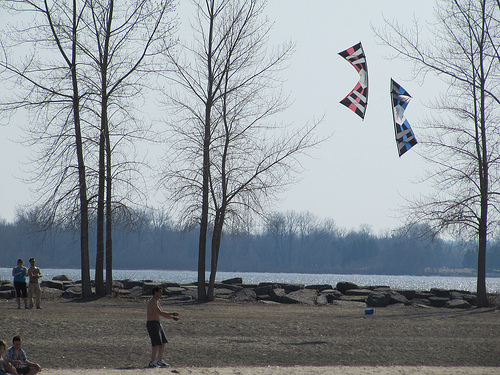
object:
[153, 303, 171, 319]
arm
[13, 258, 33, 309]
person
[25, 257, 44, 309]
person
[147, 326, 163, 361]
legs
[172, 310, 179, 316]
hand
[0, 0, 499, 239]
sky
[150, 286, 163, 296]
head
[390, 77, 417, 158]
kite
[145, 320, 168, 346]
shorts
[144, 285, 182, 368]
man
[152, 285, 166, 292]
hair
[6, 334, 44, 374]
children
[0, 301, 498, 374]
ground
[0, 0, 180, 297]
tree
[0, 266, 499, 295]
lake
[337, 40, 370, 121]
kite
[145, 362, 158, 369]
foot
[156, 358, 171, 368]
foot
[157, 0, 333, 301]
tree